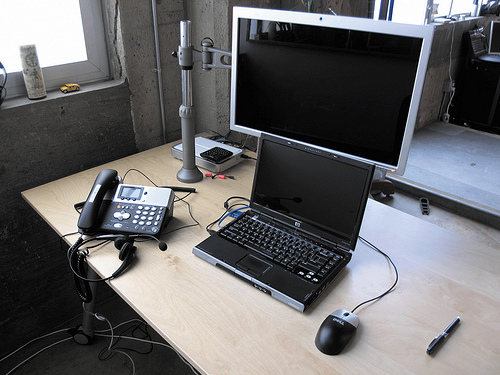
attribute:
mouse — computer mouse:
[313, 307, 357, 361]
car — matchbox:
[58, 84, 80, 95]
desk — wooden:
[15, 129, 495, 371]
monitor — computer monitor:
[163, 4, 420, 181]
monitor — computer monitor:
[226, 4, 433, 180]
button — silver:
[145, 201, 161, 218]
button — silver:
[112, 222, 121, 230]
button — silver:
[135, 205, 142, 210]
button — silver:
[140, 220, 147, 225]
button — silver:
[146, 215, 153, 220]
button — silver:
[129, 213, 141, 219]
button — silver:
[139, 214, 146, 222]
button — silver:
[113, 222, 124, 228]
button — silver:
[120, 211, 130, 219]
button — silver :
[114, 221, 124, 229]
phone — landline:
[74, 166, 175, 241]